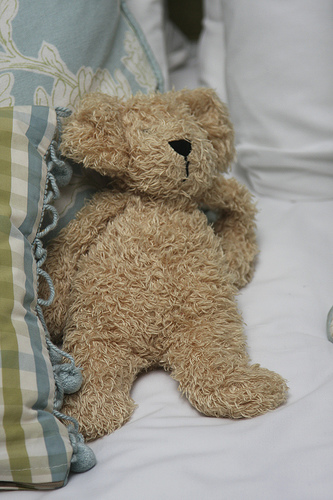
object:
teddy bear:
[34, 88, 289, 447]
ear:
[60, 94, 130, 180]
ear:
[184, 85, 235, 173]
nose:
[168, 135, 192, 158]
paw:
[39, 296, 66, 338]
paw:
[212, 241, 254, 292]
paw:
[56, 385, 139, 444]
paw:
[188, 362, 290, 421]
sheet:
[153, 427, 308, 499]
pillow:
[0, 104, 97, 494]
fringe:
[31, 262, 58, 309]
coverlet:
[2, 2, 148, 88]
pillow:
[198, 2, 332, 199]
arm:
[208, 170, 259, 292]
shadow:
[162, 0, 205, 48]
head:
[59, 86, 235, 203]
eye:
[138, 124, 146, 139]